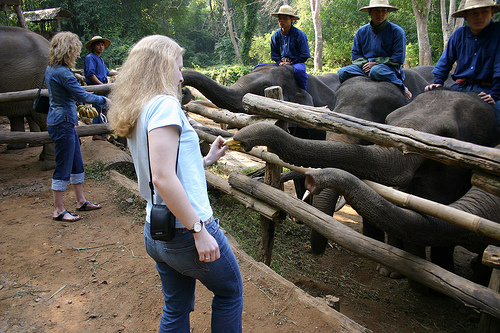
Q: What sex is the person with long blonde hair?
A: Female.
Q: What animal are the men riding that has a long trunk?
A: Elephants.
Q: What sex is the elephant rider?
A: Male.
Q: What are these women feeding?
A: Elephant.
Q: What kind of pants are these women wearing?
A: Blue jeans.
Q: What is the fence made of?
A: Wood.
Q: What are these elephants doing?
A: Eating.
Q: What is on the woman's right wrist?
A: A watch.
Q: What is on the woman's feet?
A: Sandals.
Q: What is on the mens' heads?
A: Hats.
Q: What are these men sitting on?
A: Elephants.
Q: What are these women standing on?
A: Dirt.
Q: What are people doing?
A: Feeding elephants.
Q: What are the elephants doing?
A: Eating.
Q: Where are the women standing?
A: In the dirt.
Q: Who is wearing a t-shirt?
A: The woman.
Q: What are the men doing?
A: Riding the elephants.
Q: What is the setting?
A: A zoo.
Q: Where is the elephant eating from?
A: The hand.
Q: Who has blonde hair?
A: The woman.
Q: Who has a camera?
A: The woman.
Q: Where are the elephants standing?
A: Behind the fence.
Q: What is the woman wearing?
A: Blue jeans and a light blue t-shirt.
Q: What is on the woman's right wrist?
A: A watch.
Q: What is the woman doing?
A: Feeding an elephant.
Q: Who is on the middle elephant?
A: A person in a pith helmet and a blue shirt.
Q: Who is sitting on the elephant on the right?
A: A person in a pith helmet and a blue shirt.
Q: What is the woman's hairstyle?
A: Long and blond.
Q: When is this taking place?
A: Daytime.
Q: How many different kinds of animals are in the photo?
A: One.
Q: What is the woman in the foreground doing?
A: Feeding the elephant.